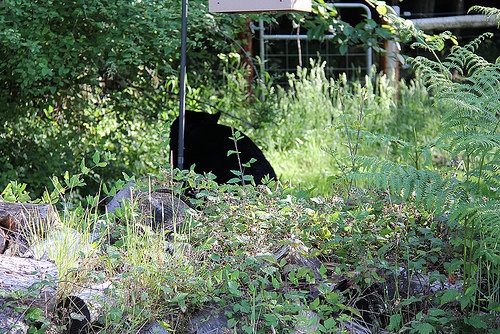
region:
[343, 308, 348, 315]
edge of a twig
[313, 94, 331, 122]
part of a fence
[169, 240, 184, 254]
part of a rock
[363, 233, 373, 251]
part of a leaf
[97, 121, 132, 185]
part of a bush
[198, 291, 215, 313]
edge of a rock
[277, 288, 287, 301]
side of a rock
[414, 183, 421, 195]
part of a leaf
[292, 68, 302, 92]
edge of a fence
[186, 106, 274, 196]
black cat with back to camera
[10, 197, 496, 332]
wood pile overgrown with ivy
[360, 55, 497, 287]
large fern growing in garden gone wild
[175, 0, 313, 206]
pole supporting a bird house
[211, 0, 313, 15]
bottom of wooden bird house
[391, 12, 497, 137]
fencing made of small logs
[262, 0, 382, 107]
metal gate in wooden fence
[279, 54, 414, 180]
tall grasses grow in front of gate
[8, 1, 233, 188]
large bush with deep green leaves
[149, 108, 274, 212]
very black cat grooming himself in an overgrown garden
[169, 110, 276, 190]
black bear on ground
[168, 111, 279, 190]
black bear by pole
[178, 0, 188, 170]
grey metal pole in ground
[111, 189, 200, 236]
white stone on ground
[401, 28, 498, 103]
green plant on ground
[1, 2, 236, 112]
tree with green leaves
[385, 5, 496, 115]
grey metal tube post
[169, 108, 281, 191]
bear cub in grass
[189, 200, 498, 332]
green weeds in rock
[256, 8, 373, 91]
green metal and wire gate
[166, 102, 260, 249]
This is a black cat that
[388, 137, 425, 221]
This is a green plant that is visible here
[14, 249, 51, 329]
This is gray logs that are visible here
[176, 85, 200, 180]
This is a small pole that is visible here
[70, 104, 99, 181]
There are green leaves in the distance here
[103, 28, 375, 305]
Jackson Mingus is the one who took the photo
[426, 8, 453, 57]
There is a silver railing in the distance here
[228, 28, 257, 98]
There is wood trim on the house in the background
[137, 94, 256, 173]
animal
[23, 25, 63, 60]
green leaves in brown trees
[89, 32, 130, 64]
green leaves in brown trees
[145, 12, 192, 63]
green leaves in brown trees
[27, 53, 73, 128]
green leaves in brown trees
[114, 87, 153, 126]
green leaves in brown trees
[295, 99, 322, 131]
green leaves in brown trees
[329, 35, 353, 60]
green leaves in brown trees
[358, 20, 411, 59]
green leaves in brown trees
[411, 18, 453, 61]
green leaves in brown trees